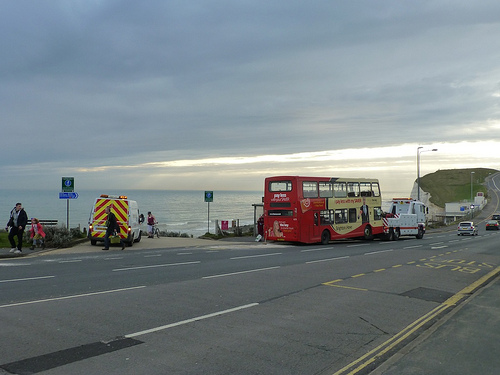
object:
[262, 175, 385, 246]
bus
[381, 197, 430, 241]
tow truck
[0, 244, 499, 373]
road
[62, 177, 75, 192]
sign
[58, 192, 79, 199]
traffic information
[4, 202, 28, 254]
man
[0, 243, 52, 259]
sidewalk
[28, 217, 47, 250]
child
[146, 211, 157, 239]
man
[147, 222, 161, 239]
bicycle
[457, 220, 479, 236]
car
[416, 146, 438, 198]
street light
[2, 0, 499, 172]
sky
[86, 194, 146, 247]
van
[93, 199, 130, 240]
doors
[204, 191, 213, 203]
sign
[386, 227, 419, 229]
stripe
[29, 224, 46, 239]
jacket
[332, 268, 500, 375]
lines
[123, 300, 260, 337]
line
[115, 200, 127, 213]
stripes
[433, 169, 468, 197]
grass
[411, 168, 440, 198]
cliff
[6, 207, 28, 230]
jacket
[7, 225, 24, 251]
pants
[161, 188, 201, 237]
water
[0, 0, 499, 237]
background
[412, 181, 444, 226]
side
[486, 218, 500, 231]
car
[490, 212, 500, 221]
car